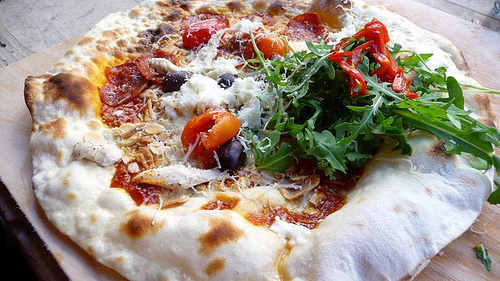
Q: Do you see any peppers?
A: Yes, there is a pepper.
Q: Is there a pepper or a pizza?
A: Yes, there is a pepper.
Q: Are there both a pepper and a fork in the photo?
A: No, there is a pepper but no forks.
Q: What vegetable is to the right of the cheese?
A: The vegetable is a pepper.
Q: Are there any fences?
A: No, there are no fences.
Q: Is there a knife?
A: No, there are no knives.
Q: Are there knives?
A: No, there are no knives.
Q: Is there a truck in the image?
A: Yes, there is a truck.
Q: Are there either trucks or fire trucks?
A: Yes, there is a truck.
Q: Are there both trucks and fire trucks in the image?
A: No, there is a truck but no fire trucks.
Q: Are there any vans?
A: No, there are no vans.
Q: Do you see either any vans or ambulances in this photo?
A: No, there are no vans or ambulances.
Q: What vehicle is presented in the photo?
A: The vehicle is a truck.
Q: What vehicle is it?
A: The vehicle is a truck.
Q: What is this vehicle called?
A: This is a truck.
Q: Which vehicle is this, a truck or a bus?
A: This is a truck.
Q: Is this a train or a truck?
A: This is a truck.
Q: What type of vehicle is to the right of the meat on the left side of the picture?
A: The vehicle is a truck.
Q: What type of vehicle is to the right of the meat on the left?
A: The vehicle is a truck.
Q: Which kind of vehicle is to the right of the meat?
A: The vehicle is a truck.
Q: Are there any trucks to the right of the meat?
A: Yes, there is a truck to the right of the meat.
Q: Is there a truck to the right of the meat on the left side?
A: Yes, there is a truck to the right of the meat.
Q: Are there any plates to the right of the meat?
A: No, there is a truck to the right of the meat.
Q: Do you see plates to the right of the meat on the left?
A: No, there is a truck to the right of the meat.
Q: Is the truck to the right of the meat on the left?
A: Yes, the truck is to the right of the meat.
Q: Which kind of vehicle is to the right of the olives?
A: The vehicle is a truck.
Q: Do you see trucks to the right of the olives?
A: Yes, there is a truck to the right of the olives.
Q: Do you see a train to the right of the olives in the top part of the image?
A: No, there is a truck to the right of the olives.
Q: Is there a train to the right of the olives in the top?
A: No, there is a truck to the right of the olives.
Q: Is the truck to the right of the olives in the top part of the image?
A: Yes, the truck is to the right of the olives.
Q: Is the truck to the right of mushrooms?
A: No, the truck is to the right of the olives.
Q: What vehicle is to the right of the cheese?
A: The vehicle is a truck.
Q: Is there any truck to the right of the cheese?
A: Yes, there is a truck to the right of the cheese.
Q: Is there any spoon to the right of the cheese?
A: No, there is a truck to the right of the cheese.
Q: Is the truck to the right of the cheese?
A: Yes, the truck is to the right of the cheese.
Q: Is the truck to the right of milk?
A: No, the truck is to the right of the cheese.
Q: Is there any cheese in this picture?
A: Yes, there is cheese.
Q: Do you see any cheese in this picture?
A: Yes, there is cheese.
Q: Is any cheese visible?
A: Yes, there is cheese.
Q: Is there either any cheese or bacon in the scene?
A: Yes, there is cheese.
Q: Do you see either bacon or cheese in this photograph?
A: Yes, there is cheese.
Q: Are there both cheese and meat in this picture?
A: Yes, there are both cheese and meat.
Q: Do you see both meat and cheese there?
A: Yes, there are both cheese and meat.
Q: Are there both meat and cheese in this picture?
A: Yes, there are both cheese and meat.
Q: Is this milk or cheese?
A: This is cheese.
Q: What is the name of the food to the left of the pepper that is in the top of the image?
A: The food is cheese.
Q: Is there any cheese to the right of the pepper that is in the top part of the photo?
A: No, the cheese is to the left of the pepper.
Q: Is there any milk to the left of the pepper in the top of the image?
A: No, there is cheese to the left of the pepper.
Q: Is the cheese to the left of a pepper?
A: Yes, the cheese is to the left of a pepper.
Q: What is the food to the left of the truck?
A: The food is cheese.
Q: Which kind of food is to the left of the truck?
A: The food is cheese.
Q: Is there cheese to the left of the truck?
A: Yes, there is cheese to the left of the truck.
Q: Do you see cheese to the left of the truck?
A: Yes, there is cheese to the left of the truck.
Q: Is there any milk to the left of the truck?
A: No, there is cheese to the left of the truck.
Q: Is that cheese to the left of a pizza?
A: No, the cheese is to the left of a truck.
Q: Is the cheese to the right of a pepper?
A: No, the cheese is to the left of a pepper.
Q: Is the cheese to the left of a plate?
A: No, the cheese is to the left of a vegetable.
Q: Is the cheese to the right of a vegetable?
A: No, the cheese is to the left of a vegetable.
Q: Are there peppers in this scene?
A: Yes, there is a pepper.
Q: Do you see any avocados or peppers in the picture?
A: Yes, there is a pepper.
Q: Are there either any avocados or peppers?
A: Yes, there is a pepper.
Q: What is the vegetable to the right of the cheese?
A: The vegetable is a pepper.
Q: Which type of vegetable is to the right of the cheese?
A: The vegetable is a pepper.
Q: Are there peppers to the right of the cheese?
A: Yes, there is a pepper to the right of the cheese.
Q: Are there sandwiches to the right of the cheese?
A: No, there is a pepper to the right of the cheese.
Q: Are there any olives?
A: Yes, there are olives.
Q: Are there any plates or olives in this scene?
A: Yes, there are olives.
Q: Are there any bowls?
A: No, there are no bowls.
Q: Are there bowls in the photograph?
A: No, there are no bowls.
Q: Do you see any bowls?
A: No, there are no bowls.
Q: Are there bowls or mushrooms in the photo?
A: No, there are no bowls or mushrooms.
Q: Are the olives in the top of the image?
A: Yes, the olives are in the top of the image.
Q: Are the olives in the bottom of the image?
A: No, the olives are in the top of the image.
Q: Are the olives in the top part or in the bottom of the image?
A: The olives are in the top of the image.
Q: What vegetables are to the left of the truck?
A: The vegetables are olives.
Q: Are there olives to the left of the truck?
A: Yes, there are olives to the left of the truck.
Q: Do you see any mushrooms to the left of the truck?
A: No, there are olives to the left of the truck.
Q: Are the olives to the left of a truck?
A: Yes, the olives are to the left of a truck.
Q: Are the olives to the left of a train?
A: No, the olives are to the left of a truck.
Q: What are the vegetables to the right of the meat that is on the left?
A: The vegetables are olives.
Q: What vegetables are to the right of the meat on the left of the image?
A: The vegetables are olives.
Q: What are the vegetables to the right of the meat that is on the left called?
A: The vegetables are olives.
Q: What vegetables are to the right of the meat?
A: The vegetables are olives.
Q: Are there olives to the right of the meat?
A: Yes, there are olives to the right of the meat.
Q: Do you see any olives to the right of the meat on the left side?
A: Yes, there are olives to the right of the meat.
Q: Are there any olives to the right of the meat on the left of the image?
A: Yes, there are olives to the right of the meat.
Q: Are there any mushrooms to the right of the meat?
A: No, there are olives to the right of the meat.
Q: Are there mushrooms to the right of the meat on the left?
A: No, there are olives to the right of the meat.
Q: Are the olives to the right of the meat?
A: Yes, the olives are to the right of the meat.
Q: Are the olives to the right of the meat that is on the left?
A: Yes, the olives are to the right of the meat.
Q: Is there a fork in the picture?
A: No, there are no forks.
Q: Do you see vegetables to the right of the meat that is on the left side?
A: Yes, there is a vegetable to the right of the meat.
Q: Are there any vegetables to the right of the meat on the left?
A: Yes, there is a vegetable to the right of the meat.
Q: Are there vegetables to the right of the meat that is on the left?
A: Yes, there is a vegetable to the right of the meat.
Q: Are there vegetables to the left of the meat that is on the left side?
A: No, the vegetable is to the right of the meat.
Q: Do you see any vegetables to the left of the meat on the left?
A: No, the vegetable is to the right of the meat.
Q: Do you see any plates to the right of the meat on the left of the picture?
A: No, there is a vegetable to the right of the meat.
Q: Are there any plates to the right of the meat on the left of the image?
A: No, there is a vegetable to the right of the meat.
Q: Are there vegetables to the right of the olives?
A: Yes, there is a vegetable to the right of the olives.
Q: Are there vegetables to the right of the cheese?
A: Yes, there is a vegetable to the right of the cheese.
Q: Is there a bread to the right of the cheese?
A: No, there is a vegetable to the right of the cheese.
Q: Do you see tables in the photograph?
A: Yes, there is a table.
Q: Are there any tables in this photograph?
A: Yes, there is a table.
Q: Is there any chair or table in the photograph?
A: Yes, there is a table.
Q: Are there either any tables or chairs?
A: Yes, there is a table.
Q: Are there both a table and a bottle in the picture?
A: No, there is a table but no bottles.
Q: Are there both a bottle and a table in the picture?
A: No, there is a table but no bottles.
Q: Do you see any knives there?
A: No, there are no knives.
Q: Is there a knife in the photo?
A: No, there are no knives.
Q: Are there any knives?
A: No, there are no knives.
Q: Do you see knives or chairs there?
A: No, there are no knives or chairs.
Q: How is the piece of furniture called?
A: The piece of furniture is a table.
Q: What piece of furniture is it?
A: The piece of furniture is a table.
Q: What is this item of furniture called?
A: This is a table.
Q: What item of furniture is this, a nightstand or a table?
A: This is a table.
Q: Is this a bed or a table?
A: This is a table.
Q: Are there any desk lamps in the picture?
A: No, there are no desk lamps.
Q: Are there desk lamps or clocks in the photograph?
A: No, there are no desk lamps or clocks.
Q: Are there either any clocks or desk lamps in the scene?
A: No, there are no desk lamps or clocks.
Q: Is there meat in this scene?
A: Yes, there is meat.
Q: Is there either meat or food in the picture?
A: Yes, there is meat.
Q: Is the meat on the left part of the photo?
A: Yes, the meat is on the left of the image.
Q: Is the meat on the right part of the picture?
A: No, the meat is on the left of the image.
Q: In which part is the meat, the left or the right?
A: The meat is on the left of the image.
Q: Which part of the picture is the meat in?
A: The meat is on the left of the image.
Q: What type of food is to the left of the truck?
A: The food is meat.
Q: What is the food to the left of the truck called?
A: The food is meat.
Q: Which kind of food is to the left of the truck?
A: The food is meat.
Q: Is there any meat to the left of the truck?
A: Yes, there is meat to the left of the truck.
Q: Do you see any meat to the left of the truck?
A: Yes, there is meat to the left of the truck.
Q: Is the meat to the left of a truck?
A: Yes, the meat is to the left of a truck.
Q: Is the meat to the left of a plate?
A: No, the meat is to the left of a truck.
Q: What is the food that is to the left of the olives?
A: The food is meat.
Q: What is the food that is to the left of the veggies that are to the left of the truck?
A: The food is meat.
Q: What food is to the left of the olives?
A: The food is meat.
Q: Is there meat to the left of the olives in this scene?
A: Yes, there is meat to the left of the olives.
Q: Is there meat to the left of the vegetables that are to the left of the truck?
A: Yes, there is meat to the left of the olives.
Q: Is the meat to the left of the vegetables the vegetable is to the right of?
A: Yes, the meat is to the left of the olives.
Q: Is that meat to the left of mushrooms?
A: No, the meat is to the left of the olives.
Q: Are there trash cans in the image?
A: No, there are no trash cans.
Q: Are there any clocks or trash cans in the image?
A: No, there are no trash cans or clocks.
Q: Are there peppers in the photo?
A: Yes, there is a pepper.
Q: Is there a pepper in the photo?
A: Yes, there is a pepper.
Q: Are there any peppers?
A: Yes, there is a pepper.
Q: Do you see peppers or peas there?
A: Yes, there is a pepper.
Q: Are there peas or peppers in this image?
A: Yes, there is a pepper.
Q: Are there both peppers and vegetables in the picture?
A: Yes, there are both a pepper and vegetables.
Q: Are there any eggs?
A: No, there are no eggs.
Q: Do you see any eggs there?
A: No, there are no eggs.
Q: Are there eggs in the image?
A: No, there are no eggs.